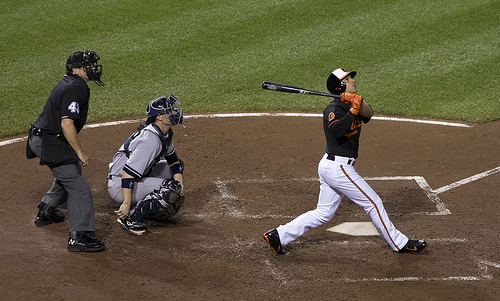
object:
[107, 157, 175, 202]
pants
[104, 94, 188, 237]
catcher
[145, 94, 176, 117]
helmet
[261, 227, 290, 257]
shoe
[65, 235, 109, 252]
black shoe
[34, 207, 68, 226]
black shoe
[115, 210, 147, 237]
shoes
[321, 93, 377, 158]
shirt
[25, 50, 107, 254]
umpire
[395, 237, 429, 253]
black shoe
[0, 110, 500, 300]
dirt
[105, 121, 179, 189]
shirt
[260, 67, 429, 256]
batter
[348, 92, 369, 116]
gloves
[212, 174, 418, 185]
line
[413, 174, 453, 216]
line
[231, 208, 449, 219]
line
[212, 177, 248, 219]
line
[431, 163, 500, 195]
line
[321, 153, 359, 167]
belt